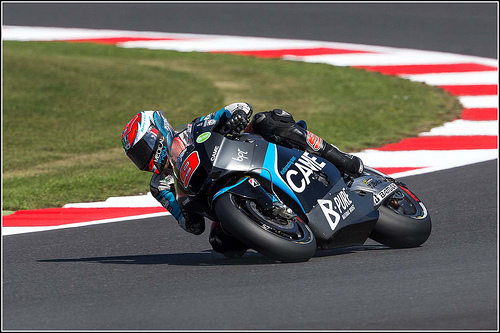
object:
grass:
[288, 95, 356, 131]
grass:
[26, 74, 135, 163]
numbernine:
[173, 144, 211, 194]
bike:
[166, 129, 443, 261]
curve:
[0, 10, 499, 235]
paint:
[0, 204, 167, 228]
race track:
[5, 7, 499, 329]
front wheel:
[209, 186, 318, 263]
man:
[120, 102, 362, 257]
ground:
[384, 70, 422, 104]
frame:
[176, 132, 395, 250]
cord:
[238, 165, 286, 207]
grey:
[71, 253, 168, 309]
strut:
[376, 176, 424, 219]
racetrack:
[66, 219, 466, 311]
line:
[392, 55, 499, 95]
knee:
[252, 111, 288, 136]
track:
[106, 238, 390, 313]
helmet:
[122, 110, 174, 174]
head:
[119, 108, 177, 175]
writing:
[316, 188, 365, 231]